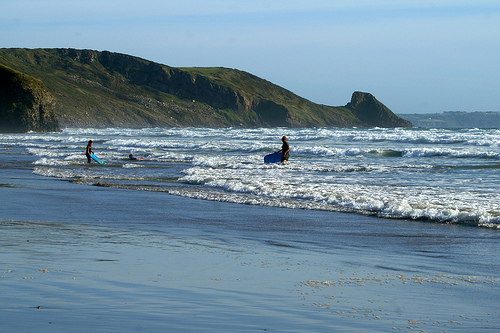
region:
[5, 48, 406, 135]
steep rocky outcrop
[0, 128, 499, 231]
rough whitecapped ocean water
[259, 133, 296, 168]
person with a blue boogie board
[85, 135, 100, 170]
person with a blue boogie board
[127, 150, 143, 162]
person lying down in surf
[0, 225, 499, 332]
wet beach with tide coming in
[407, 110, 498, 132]
distant rocky shore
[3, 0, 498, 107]
blue hazy sky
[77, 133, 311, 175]
family enjoying the surf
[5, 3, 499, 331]
isolated beach in a rocky inlet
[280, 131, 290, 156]
A person in the sea water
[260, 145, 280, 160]
A surf board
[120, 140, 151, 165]
A person on the waters surfing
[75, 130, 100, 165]
A woman holding a surfing board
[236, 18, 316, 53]
Blue skies in the photo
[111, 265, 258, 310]
Sand in the photo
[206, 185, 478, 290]
A coastline in the photo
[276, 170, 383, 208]
Strong tides in the ocean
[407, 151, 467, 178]
Sea waters in the photo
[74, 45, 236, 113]
Hills in the background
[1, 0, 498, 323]
a scene outside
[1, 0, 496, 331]
a image at the beach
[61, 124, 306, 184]
a couple of people in the water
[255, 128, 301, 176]
a person holding a surfboard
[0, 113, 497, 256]
white waves all across the water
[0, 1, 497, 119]
a blue sky with a hint of clouds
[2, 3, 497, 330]
a scene during the day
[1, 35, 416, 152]
some hills in the background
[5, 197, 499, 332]
a wet shoreline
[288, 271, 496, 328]
foam bubbles on the sand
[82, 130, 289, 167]
three people in the ocean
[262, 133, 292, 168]
man holding a dark blue boogey board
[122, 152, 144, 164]
person laying on their stomache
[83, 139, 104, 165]
woman holding a light blue boogey board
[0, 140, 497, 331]
wet and sandy beach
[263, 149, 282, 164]
dark blue boogey board in the man's hand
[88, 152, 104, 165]
light blue boogey board held by the woman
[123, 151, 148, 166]
person wearing red trunks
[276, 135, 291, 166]
man wearing black in the ocean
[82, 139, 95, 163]
woman wearing black in the ocean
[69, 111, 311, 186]
Two surfers in the ocean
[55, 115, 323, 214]
Men surfing in the ocean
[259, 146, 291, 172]
A blue surfboard in the man's hands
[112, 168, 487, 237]
Waves crashing along the shore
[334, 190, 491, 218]
White sea foam on the heads of the waves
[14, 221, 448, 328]
The shore in front of the ocean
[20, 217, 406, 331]
Water covering the sand of the beach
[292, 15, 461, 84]
A patch of clear blue sky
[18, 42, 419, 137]
A large cliff in the distance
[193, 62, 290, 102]
Grass covering the distant cliff